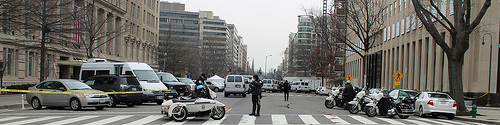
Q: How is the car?
A: Parked.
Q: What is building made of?
A: Brick.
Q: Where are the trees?
A: Along curb.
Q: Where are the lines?
A: On road.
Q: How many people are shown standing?
A: Two.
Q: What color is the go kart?
A: White.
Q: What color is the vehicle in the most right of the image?
A: White.